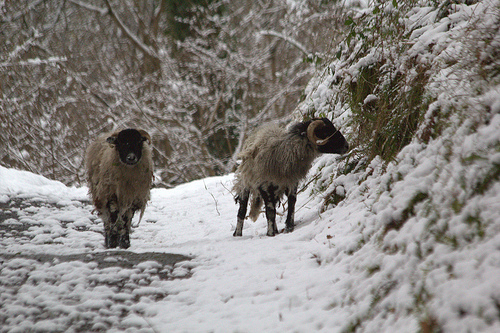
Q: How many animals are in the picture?
A: Two.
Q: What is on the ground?
A: Snow.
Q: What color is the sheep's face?
A: Black.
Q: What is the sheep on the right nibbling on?
A: Green bush.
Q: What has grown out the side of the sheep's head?
A: Horns.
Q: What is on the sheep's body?
A: Wool.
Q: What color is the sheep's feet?
A: Black.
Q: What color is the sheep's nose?
A: White.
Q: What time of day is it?
A: Morning.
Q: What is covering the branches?
A: Snow.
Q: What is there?
A: Animals.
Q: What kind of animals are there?
A: Sheep.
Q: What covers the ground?
A: Snow.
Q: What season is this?
A: Winter.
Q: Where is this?
A: Snowy path.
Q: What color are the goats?
A: Brown.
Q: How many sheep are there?
A: 2.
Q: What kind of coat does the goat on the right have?
A: Shaggy.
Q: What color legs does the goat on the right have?
A: Black.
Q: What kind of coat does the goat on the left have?
A: Shaggy.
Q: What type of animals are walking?
A: Mountain goats.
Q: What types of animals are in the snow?
A: Rams.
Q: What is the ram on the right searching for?
A: Food.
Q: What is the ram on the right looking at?
A: Snowy hill.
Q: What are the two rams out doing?
A: Stroll.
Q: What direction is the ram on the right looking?
A: Left.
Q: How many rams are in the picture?
A: 2.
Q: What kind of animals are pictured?
A: Rams.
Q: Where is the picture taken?
A: Outside in a woods.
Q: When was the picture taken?
A: Winter.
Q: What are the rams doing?
A: Walking in the snow.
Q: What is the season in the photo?
A: Winter.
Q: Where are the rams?
A: Path.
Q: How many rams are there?
A: 2.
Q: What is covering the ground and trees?
A: Snow.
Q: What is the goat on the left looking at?
A: The camera.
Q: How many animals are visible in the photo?
A: 2.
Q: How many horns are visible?
A: 1.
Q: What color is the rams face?
A: Black.